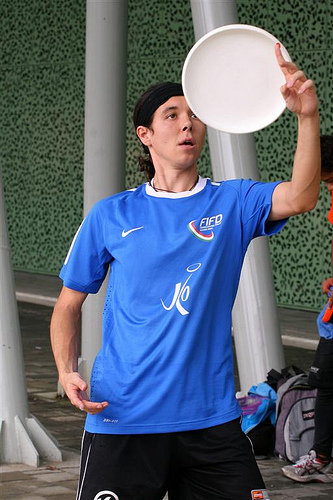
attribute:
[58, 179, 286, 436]
shirt — blue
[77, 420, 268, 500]
shorts — black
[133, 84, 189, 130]
head band — black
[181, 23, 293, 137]
frisbee — white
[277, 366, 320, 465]
backpack — grey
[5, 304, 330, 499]
ground — concrete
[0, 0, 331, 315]
wall — green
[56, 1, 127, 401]
pole — gray